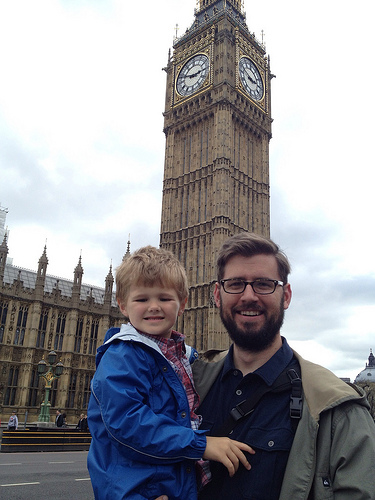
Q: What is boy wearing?
A: Jacket.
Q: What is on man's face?
A: Glasses.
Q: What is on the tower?
A: Clock.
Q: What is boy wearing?
A: Jacket.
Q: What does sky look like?
A: Cloudy.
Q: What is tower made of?
A: Stone.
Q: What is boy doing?
A: Smiling.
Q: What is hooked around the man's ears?
A: Eyeglasses.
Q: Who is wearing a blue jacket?
A: Boy.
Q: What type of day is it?
A: Cloudy.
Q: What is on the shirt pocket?
A: Button.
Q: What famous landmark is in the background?
A: Big Ben.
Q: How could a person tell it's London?
A: Big Ben.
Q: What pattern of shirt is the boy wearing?
A: Plaid.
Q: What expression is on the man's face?
A: Smile.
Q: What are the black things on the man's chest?
A: Straps.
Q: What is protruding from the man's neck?
A: Adam's apple.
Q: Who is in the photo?
A: A man and boy.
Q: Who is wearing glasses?
A: The man.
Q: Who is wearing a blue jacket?
A: The boy.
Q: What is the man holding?
A: A blond boy.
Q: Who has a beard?
A: The man.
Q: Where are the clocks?
A: On the clock tower.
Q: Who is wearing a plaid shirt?
A: The boy.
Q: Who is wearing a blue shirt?
A: The man.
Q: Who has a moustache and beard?
A: The man.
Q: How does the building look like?
A: Tall.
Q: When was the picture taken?
A: Daytime.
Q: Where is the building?
A: On the left side.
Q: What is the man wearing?
A: Sunglasses.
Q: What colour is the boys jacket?
A: Blue.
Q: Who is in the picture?
A: A man and a boy.